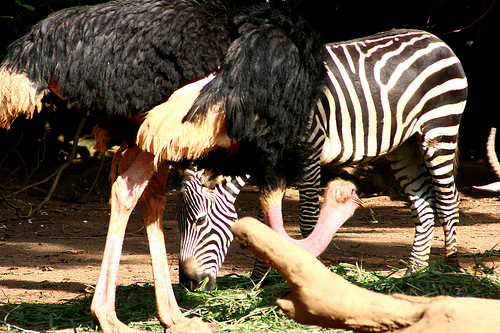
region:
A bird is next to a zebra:
[144, 47, 489, 229]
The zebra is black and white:
[184, 163, 309, 263]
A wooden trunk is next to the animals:
[222, 217, 415, 332]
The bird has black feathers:
[22, 25, 192, 102]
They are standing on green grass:
[49, 295, 339, 305]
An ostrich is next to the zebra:
[278, 180, 393, 240]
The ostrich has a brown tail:
[5, 48, 44, 142]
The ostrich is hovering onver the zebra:
[195, 55, 433, 228]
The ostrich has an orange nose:
[277, 157, 432, 314]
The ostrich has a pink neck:
[270, 201, 372, 266]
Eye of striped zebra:
[191, 213, 211, 228]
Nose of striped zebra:
[181, 270, 198, 291]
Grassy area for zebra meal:
[205, 289, 262, 317]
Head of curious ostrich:
[318, 177, 361, 228]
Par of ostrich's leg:
[95, 183, 131, 328]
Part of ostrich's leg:
[142, 220, 175, 329]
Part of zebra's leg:
[429, 134, 462, 263]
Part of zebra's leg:
[396, 171, 434, 268]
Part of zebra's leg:
[299, 167, 319, 217]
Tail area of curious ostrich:
[1, 37, 41, 141]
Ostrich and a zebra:
[5, 5, 487, 322]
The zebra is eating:
[170, 173, 249, 306]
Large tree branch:
[231, 200, 491, 331]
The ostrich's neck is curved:
[253, 150, 375, 265]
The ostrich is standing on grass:
[80, 252, 246, 330]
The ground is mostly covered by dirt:
[8, 203, 96, 293]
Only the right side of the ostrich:
[5, 8, 363, 323]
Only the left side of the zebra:
[167, 17, 479, 283]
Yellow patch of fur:
[2, 62, 51, 129]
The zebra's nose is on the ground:
[172, 260, 202, 295]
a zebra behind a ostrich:
[6, 8, 478, 314]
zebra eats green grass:
[173, 167, 240, 306]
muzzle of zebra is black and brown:
[172, 248, 222, 303]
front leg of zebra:
[293, 165, 325, 227]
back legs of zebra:
[390, 157, 471, 282]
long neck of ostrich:
[264, 185, 339, 257]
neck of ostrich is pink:
[258, 195, 334, 256]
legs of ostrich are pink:
[82, 150, 183, 330]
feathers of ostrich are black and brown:
[0, 2, 320, 197]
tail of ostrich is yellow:
[1, 60, 41, 128]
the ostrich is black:
[20, 12, 311, 226]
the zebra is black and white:
[340, 31, 464, 202]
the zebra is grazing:
[181, 44, 448, 264]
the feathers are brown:
[142, 93, 228, 166]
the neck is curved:
[262, 206, 361, 247]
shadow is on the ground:
[346, 229, 409, 263]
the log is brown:
[231, 221, 488, 330]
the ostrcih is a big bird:
[4, 11, 374, 318]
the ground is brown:
[10, 216, 80, 281]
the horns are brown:
[475, 134, 498, 171]